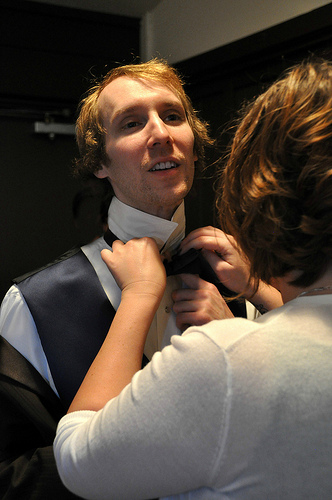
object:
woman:
[54, 62, 332, 499]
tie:
[103, 228, 202, 276]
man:
[1, 55, 276, 499]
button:
[163, 304, 175, 314]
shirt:
[0, 195, 269, 419]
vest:
[13, 244, 249, 461]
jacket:
[0, 335, 85, 499]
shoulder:
[1, 240, 109, 338]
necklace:
[297, 285, 332, 299]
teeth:
[151, 159, 179, 170]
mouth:
[146, 155, 184, 178]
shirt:
[53, 293, 331, 499]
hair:
[75, 55, 215, 180]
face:
[96, 72, 195, 207]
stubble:
[109, 148, 196, 208]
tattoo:
[254, 302, 268, 314]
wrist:
[245, 280, 284, 314]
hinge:
[3, 105, 79, 140]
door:
[1, 106, 114, 303]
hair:
[200, 47, 331, 302]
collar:
[108, 196, 186, 256]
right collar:
[107, 196, 180, 255]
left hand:
[172, 272, 236, 328]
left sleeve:
[53, 331, 227, 498]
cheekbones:
[109, 120, 196, 162]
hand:
[99, 237, 169, 294]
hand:
[178, 225, 253, 293]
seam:
[178, 326, 232, 487]